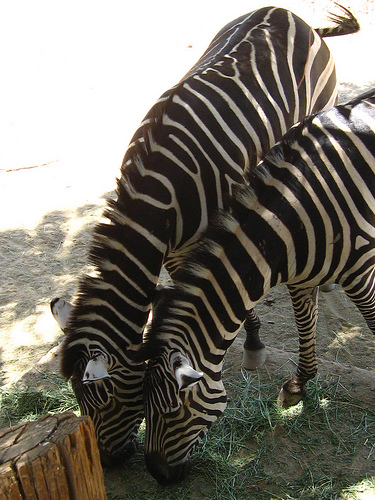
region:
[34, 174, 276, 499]
the zebras are eating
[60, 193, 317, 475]
the zebras are stripes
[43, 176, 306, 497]
the zebras are black and white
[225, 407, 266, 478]
the zebras are green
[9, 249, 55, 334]
the ground is brown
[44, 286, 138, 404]
the zebra's ears are white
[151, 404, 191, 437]
zebra's eye is black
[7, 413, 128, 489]
the wood is brown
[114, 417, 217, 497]
the zebra has nose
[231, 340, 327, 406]
the zebra has hooves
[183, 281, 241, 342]
neck of a zebra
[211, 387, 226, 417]
jaw of a zebra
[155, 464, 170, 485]
nose of a zebra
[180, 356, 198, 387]
left ear of a zebra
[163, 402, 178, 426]
left eye of a zebra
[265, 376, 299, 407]
hoof of a zebra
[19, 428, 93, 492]
part of a tree trunk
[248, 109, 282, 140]
stomach of a zebra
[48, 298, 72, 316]
right ear of a zebra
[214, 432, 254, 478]
part of some grass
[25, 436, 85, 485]
stem of a tree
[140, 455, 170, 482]
nose of a zebra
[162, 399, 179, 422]
left ear of a zebra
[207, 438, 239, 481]
part of some grass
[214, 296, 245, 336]
neck of a zebra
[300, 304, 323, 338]
right leg of a giraffe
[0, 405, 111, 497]
brown wooden stump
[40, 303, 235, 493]
two zebra heads grazing grass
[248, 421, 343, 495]
green grass clippings on brown dirt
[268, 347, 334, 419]
black and white zebra hoof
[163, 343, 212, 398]
black and white zebra ear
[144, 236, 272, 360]
black and white zebra mane and neck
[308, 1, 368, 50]
black and white zebra tail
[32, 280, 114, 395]
pair of black and white zebra ears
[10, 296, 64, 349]
patch of bright sunlight on brown ground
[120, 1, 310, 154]
back of a black and white zebra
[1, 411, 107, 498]
Top of a wooden post.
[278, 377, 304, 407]
Hoof of a zebra.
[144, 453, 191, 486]
Snout of a zebra.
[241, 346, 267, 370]
Hoof of a zebra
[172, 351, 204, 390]
Left ear of a zebra.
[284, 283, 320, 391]
Leg of a zebra.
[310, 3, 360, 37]
The tail of a zebra.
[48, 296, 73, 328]
Right ear of a zebra.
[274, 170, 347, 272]
Black and white pattern on zebra.